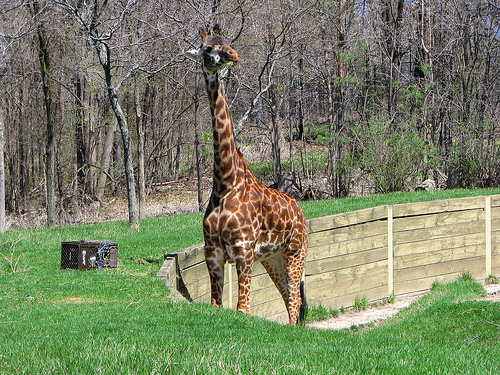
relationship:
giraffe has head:
[184, 22, 312, 329] [184, 20, 241, 72]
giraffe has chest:
[184, 22, 312, 329] [202, 186, 247, 255]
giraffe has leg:
[184, 22, 312, 329] [203, 242, 230, 310]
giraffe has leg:
[184, 22, 312, 329] [261, 250, 289, 315]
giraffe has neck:
[184, 22, 312, 329] [204, 70, 261, 187]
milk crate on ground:
[58, 237, 120, 273] [3, 188, 498, 375]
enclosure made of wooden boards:
[153, 188, 499, 341] [164, 192, 500, 325]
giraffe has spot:
[184, 22, 312, 329] [215, 118, 226, 130]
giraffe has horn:
[184, 22, 312, 329] [196, 24, 208, 38]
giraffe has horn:
[184, 22, 312, 329] [210, 23, 222, 37]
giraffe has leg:
[184, 22, 312, 329] [234, 252, 254, 316]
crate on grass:
[58, 237, 120, 273] [3, 188, 498, 375]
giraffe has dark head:
[184, 22, 312, 329] [184, 20, 241, 72]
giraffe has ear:
[184, 22, 312, 329] [184, 48, 203, 67]